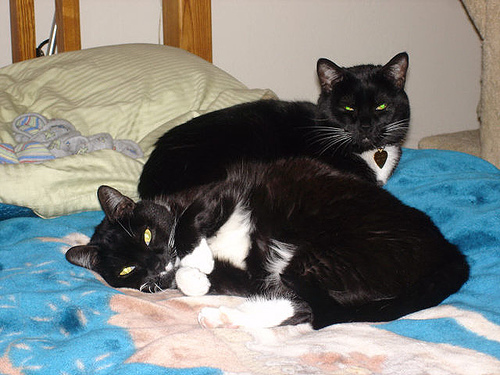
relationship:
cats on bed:
[250, 62, 411, 329] [445, 156, 499, 228]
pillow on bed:
[108, 39, 176, 106] [445, 156, 499, 228]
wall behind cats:
[251, 8, 282, 44] [250, 62, 411, 329]